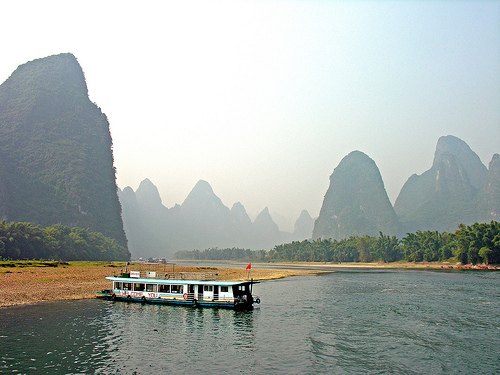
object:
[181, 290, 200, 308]
rail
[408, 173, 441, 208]
wall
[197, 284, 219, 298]
door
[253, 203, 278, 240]
mountain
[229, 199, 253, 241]
mountain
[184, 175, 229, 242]
mountain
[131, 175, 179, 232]
mountain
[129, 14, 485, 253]
distance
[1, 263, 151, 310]
sand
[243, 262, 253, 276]
flag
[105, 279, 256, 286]
roof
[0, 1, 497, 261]
cloud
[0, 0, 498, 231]
sky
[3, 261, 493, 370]
blue water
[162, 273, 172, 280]
inflation device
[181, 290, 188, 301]
inflation device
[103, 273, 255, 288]
deck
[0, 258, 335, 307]
beach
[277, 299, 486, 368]
waves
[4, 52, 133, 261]
hill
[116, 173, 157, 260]
hill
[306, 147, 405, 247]
hill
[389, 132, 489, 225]
hill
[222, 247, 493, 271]
side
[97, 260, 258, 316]
boat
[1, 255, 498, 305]
shore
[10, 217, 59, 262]
tree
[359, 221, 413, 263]
tree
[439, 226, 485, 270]
tree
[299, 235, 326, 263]
tree